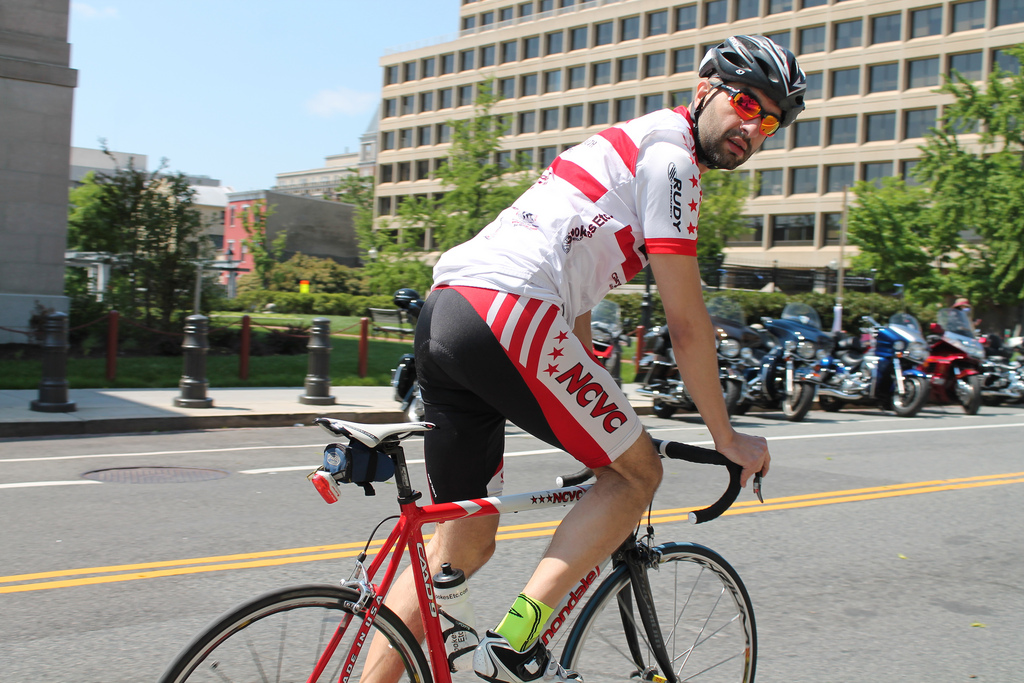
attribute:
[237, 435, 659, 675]
bike frame — red, white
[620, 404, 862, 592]
handle bars — black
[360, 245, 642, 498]
shorts — red, white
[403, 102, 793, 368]
jersey — white, red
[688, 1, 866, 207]
helmet — black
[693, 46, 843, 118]
helmet — dark, safety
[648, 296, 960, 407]
bikes — parked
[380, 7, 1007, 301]
building — high storied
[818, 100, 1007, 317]
leaves — dark green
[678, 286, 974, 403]
bikes — parked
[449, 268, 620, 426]
stripes — white, red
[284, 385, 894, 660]
bike — red, white, black